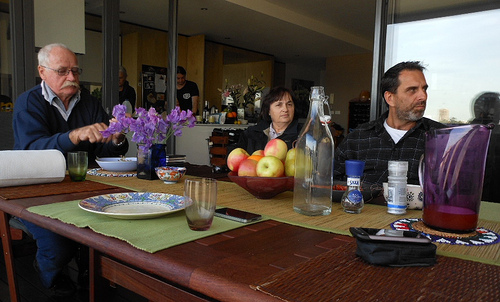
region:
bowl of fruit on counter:
[214, 128, 353, 210]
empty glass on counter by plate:
[171, 174, 241, 241]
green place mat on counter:
[54, 159, 211, 284]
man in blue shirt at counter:
[29, 54, 146, 189]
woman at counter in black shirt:
[196, 71, 316, 196]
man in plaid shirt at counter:
[356, 44, 432, 210]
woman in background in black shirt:
[131, 47, 236, 133]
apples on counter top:
[181, 122, 336, 199]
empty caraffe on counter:
[304, 79, 348, 239]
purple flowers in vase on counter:
[106, 101, 211, 181]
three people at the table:
[20, 40, 470, 188]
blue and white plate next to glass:
[23, 180, 260, 258]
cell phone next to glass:
[21, 175, 268, 272]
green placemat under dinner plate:
[19, 181, 294, 256]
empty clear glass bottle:
[288, 84, 337, 233]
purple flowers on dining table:
[96, 91, 209, 182]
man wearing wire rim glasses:
[28, 35, 102, 151]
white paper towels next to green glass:
[1, 130, 107, 192]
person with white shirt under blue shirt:
[339, 60, 461, 206]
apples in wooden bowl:
[217, 132, 324, 209]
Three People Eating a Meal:
[13, 22, 479, 272]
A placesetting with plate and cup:
[68, 175, 253, 272]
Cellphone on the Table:
[333, 211, 449, 273]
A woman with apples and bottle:
[218, 69, 349, 229]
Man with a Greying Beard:
[323, 36, 449, 219]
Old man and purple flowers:
[12, 21, 214, 197]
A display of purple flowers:
[93, 77, 213, 204]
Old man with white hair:
[6, 29, 131, 203]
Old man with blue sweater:
[6, 15, 189, 185]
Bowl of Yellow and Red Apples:
[208, 102, 330, 210]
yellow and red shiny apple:
[227, 146, 249, 171]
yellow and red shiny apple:
[236, 156, 257, 177]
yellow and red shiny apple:
[255, 158, 281, 179]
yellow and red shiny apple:
[262, 139, 289, 159]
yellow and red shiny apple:
[285, 156, 310, 175]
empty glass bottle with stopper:
[292, 84, 332, 220]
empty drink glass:
[182, 176, 219, 231]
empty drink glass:
[67, 150, 89, 182]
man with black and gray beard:
[329, 62, 460, 199]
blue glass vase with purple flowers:
[100, 99, 191, 177]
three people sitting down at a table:
[29, 38, 496, 276]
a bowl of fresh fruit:
[228, 134, 288, 203]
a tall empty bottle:
[289, 82, 336, 222]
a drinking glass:
[184, 177, 214, 234]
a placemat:
[97, 217, 188, 245]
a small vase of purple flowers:
[104, 103, 191, 178]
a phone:
[214, 205, 263, 225]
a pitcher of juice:
[414, 121, 491, 237]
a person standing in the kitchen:
[174, 62, 202, 117]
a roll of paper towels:
[1, 150, 68, 187]